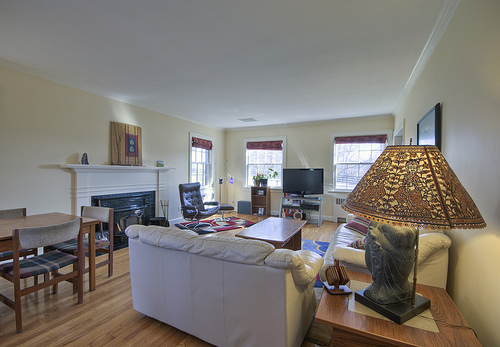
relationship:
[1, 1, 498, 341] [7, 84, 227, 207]
house has wall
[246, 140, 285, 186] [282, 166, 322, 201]
window beside television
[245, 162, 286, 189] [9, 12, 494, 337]
window at end of room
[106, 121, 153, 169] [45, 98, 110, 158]
picture on wall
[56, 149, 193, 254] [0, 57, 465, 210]
fireplace on wall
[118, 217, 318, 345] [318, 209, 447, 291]
couch by couch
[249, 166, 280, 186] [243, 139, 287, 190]
plants in front of window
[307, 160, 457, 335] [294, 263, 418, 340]
lamp on table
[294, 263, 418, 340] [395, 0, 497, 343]
table near wall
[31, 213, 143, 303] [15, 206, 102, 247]
chairs around table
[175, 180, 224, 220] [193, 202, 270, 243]
chair on carpet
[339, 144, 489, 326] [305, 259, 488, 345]
lamp on table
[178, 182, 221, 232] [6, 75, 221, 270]
chair near wall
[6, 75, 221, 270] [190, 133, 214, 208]
wall beside window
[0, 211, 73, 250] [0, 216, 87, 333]
table and chairs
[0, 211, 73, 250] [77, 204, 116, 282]
table and chairs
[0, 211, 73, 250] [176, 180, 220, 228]
table and chairs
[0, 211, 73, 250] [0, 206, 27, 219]
table and chairs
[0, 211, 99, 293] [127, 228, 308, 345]
table in front of couch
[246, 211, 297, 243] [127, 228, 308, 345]
table in front of couch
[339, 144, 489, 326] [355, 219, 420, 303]
lamp on a figurine